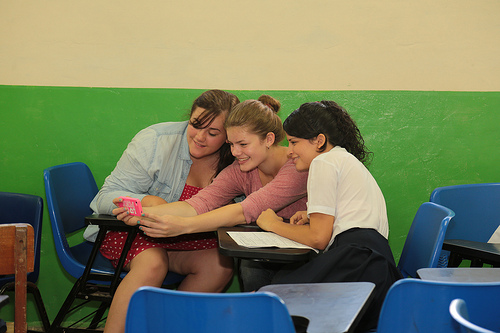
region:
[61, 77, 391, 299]
three young girls posing for a camera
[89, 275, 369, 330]
a blue desk chair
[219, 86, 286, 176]
a young girl with her hair in a bun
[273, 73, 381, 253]
a young girl wearing a white shirt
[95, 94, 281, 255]
a young girl holding a cell phone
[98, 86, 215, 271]
a young girl wearing a red and white dress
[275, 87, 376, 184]
a young girl with black hair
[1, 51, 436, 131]
a green and tan wall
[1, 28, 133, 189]
half of a wall painted green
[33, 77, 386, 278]
three girls taking their picture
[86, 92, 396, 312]
three girls are looking at a hand held device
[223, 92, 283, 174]
the girl's hair is in a bun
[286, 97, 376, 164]
the girl has a black ponytail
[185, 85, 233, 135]
the girl has brown bangs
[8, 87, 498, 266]
the wall is painted green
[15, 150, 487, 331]
blue desks are in the room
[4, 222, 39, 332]
a wooden chair is in the room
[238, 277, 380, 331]
a folding desk table in the classroom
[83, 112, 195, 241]
the schoolgirl is wearing a blue jean shirt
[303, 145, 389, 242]
a white blouse is worn by the girl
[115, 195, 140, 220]
a pink cell phone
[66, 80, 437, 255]
group of girls taking a picture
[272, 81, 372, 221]
dark haired girl in white shirt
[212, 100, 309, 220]
blonde girl in maroon shirt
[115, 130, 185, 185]
A denim jacket on one of the girls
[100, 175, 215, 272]
red and white polka dot dress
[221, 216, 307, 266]
A school desk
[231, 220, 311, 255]
A paper resting on the desk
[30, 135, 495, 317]
blue school chairs throughout the room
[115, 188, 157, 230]
turquoise painted fingernails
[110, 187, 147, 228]
hot pink cell phone cover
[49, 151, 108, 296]
hard blue straight back chair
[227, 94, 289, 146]
girls brown hair pulled into bun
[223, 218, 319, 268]
whsite papers laying on desk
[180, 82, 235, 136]
girls brown bangs hanging down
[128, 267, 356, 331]
empty chair with attached desk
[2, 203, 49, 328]
back to brown wooden chair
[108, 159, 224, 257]
girl wearing red dress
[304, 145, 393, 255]
girls white shirt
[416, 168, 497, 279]
empty chair with desk attached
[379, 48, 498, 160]
wall painted green and yellow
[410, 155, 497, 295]
blue chair at desk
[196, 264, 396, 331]
desk top attached to chair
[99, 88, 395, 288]
three girls with cell phone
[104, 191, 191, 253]
hands holding pink cell phone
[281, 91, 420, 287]
girl with dark-haired ponytail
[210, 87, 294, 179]
girl with brown hair in bun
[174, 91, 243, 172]
girl with brown bangs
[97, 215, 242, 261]
red with white polka dots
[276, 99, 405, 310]
girl wearing white shirt